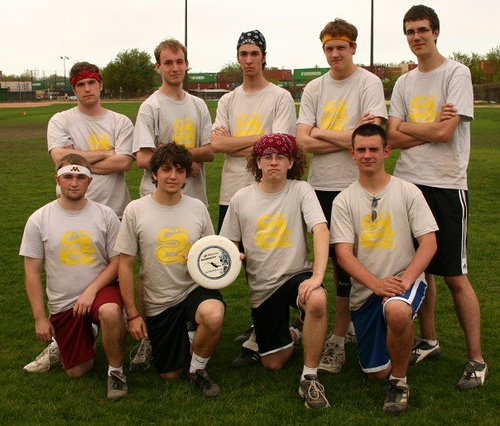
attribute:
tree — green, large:
[99, 46, 156, 99]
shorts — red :
[42, 283, 124, 368]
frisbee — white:
[184, 234, 244, 289]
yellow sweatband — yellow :
[318, 30, 354, 52]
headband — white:
[46, 166, 106, 185]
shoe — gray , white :
[456, 357, 490, 391]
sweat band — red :
[69, 68, 102, 85]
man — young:
[329, 124, 439, 411]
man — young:
[216, 135, 333, 413]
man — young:
[382, 4, 489, 392]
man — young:
[113, 142, 224, 402]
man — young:
[18, 153, 130, 403]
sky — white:
[3, 5, 498, 81]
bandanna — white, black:
[233, 25, 268, 52]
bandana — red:
[248, 135, 301, 161]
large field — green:
[1, 105, 498, 422]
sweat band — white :
[53, 161, 92, 180]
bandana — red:
[68, 70, 103, 85]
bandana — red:
[251, 132, 295, 153]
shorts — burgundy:
[34, 286, 124, 391]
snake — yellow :
[160, 229, 185, 276]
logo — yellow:
[56, 225, 95, 266]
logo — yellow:
[154, 223, 188, 264]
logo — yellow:
[253, 209, 291, 253]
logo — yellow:
[359, 210, 393, 254]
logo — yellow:
[82, 129, 110, 157]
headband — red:
[67, 68, 98, 79]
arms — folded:
[53, 140, 130, 171]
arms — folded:
[135, 140, 215, 176]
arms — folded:
[210, 120, 282, 159]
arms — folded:
[292, 118, 362, 156]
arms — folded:
[387, 106, 464, 146]